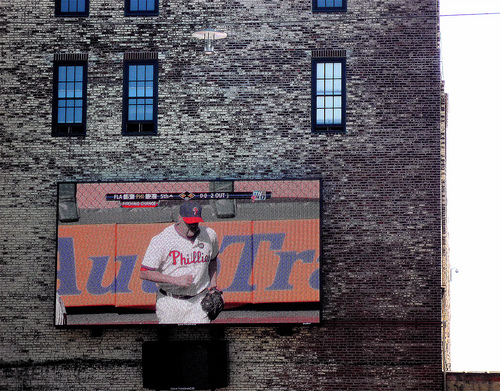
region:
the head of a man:
[172, 179, 224, 254]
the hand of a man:
[171, 262, 203, 299]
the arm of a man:
[127, 229, 213, 301]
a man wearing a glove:
[191, 240, 256, 316]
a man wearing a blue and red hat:
[166, 185, 238, 242]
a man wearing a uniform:
[157, 189, 262, 308]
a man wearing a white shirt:
[138, 197, 260, 306]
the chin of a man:
[172, 223, 206, 250]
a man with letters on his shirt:
[157, 223, 279, 282]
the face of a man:
[173, 208, 215, 249]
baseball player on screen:
[139, 196, 236, 328]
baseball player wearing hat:
[170, 198, 212, 225]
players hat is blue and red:
[176, 195, 208, 228]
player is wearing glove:
[196, 281, 229, 320]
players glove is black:
[198, 281, 227, 319]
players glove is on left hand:
[197, 282, 230, 327]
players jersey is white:
[136, 217, 230, 327]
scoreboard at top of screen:
[101, 186, 273, 207]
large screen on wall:
[36, 171, 326, 335]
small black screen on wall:
[128, 333, 233, 389]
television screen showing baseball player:
[49, 176, 324, 328]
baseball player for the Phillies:
[157, 198, 219, 315]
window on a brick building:
[307, 47, 347, 136]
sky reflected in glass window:
[51, 43, 162, 133]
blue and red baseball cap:
[180, 201, 200, 228]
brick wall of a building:
[334, 208, 423, 340]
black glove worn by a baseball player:
[202, 288, 225, 318]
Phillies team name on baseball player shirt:
[169, 246, 215, 266]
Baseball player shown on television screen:
[139, 198, 226, 323]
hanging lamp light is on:
[189, 17, 229, 57]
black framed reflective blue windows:
[43, 45, 96, 146]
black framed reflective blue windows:
[119, 45, 167, 144]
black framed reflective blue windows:
[299, 43, 353, 137]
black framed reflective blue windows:
[53, 2, 94, 23]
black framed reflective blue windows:
[119, 0, 162, 17]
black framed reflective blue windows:
[309, 3, 351, 16]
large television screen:
[50, 179, 337, 334]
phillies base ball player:
[134, 199, 236, 337]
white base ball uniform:
[135, 218, 226, 339]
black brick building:
[1, 5, 439, 389]